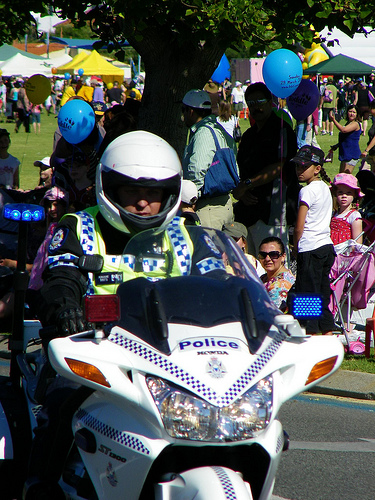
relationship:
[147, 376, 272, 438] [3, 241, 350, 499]
front headlight on motorcycle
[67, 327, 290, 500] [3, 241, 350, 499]
stripe on motorcycle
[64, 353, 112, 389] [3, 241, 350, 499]
light on a motorcycle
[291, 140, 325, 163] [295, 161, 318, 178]
hat on head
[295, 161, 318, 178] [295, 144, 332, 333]
head of girl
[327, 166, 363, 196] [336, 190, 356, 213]
hat on head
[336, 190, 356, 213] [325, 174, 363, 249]
head of girl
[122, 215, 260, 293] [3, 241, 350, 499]
windshield on motorcycle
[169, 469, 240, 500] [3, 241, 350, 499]
fender on motorcycle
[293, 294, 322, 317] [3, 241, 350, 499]
light on motorcycle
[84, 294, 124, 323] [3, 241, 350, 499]
light on motorcycle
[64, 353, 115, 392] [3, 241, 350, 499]
light on motorcycle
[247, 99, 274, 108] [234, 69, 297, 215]
sunglasses worn by man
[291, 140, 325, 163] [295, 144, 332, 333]
hat on girl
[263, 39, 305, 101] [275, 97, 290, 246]
balloon on a string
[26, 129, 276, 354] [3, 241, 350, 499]
police officer on motorcycle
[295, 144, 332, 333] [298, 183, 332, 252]
girl wears shirt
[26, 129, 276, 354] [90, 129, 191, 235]
police officer wears helmet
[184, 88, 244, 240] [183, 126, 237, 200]
person holding bag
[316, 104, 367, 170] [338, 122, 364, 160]
woman wears top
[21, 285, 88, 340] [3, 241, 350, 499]
handles of motorcycle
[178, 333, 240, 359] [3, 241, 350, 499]
police on motorcycle